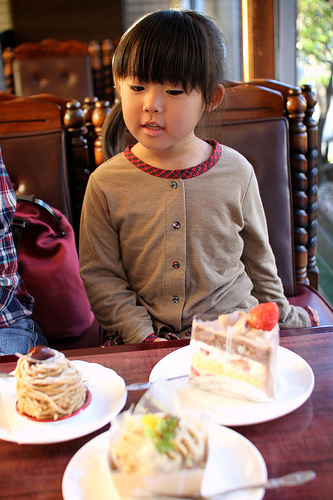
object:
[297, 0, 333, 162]
tree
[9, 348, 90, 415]
noodle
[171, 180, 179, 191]
button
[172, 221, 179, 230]
button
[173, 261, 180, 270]
button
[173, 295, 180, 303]
button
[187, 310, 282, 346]
wax paper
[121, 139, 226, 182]
trim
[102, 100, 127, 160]
ponytail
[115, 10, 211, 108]
bangs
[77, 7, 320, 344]
girl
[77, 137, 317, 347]
shirt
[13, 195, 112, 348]
bag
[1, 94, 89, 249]
chair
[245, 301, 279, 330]
strawberry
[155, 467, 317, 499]
fork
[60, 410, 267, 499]
plant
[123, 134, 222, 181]
collar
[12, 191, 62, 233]
handle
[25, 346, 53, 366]
plum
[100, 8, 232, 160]
hair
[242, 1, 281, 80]
door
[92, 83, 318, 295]
chair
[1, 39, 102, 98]
chair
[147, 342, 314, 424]
plate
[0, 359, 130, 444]
plate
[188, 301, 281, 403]
cake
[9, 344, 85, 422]
cake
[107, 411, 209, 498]
cake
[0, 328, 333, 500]
table